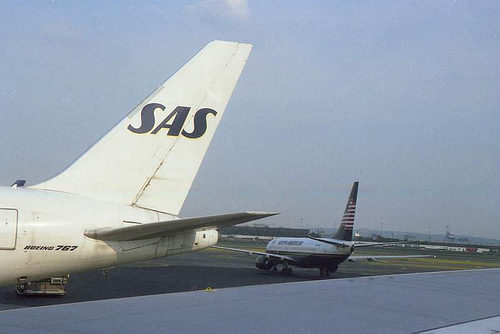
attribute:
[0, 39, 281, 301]
plane — parked, white, dirty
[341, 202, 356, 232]
flag — red white, blue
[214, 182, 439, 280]
plane — parked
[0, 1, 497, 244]
sky — blue, clear, white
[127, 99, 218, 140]
text — black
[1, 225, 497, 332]
ground — gray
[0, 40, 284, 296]
airplane — white, being loaded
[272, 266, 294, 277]
wheels — black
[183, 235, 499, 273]
grass — green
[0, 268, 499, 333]
sidewalk — gray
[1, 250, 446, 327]
tarmac — gray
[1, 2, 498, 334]
airport — big, massive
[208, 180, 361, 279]
airplane — parked